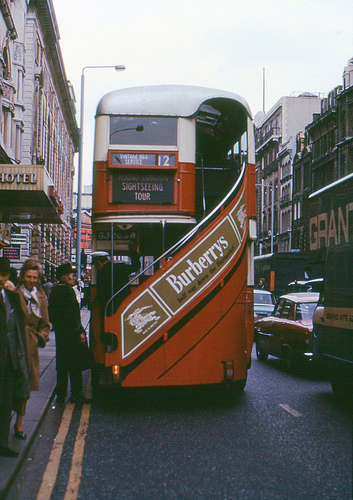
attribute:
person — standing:
[47, 260, 96, 404]